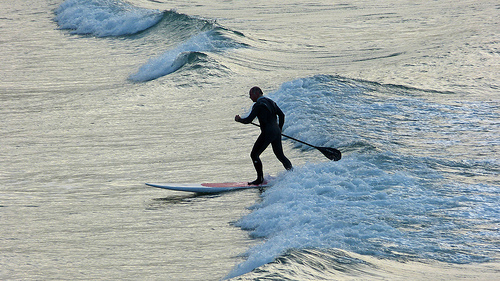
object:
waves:
[45, 0, 273, 92]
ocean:
[0, 0, 499, 158]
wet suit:
[233, 98, 294, 184]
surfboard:
[142, 178, 270, 195]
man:
[232, 85, 297, 185]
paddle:
[234, 111, 344, 162]